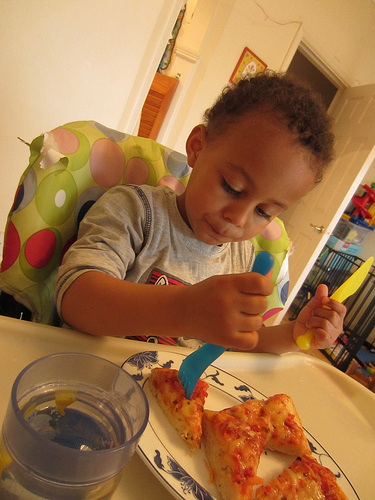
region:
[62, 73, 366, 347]
child eating pizza slices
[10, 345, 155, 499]
cup on the tray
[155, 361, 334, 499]
pizza slices on the plate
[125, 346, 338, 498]
white plate with blue design on border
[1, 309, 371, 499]
tray of the high chair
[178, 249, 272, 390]
blue fork child is eating with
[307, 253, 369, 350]
yellow knife in child's hand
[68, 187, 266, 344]
gray shirt child is wearing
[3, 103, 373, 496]
high chair child is sitting in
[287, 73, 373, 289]
white door to the room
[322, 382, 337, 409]
part of a plate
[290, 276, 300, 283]
part of a door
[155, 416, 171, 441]
edge of a plate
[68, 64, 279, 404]
a child in a high chair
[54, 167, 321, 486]
a child sitting in high chair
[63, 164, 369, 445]
a child eatting in high chair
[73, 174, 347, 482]
a child holding plastic fork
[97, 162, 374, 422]
a child holding a blue fork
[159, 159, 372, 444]
a child holding yellow knife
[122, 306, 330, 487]
food on a plate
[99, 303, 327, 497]
a plate with food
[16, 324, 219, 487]
a drink on the high chair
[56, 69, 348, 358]
toddler eating in a highchair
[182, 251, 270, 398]
blue plastic fork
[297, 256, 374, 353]
yellow plastic knife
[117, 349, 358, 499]
white plate with blue decorations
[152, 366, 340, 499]
pizza cut into small pieces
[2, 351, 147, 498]
clear cup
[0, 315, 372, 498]
white tray of the highchair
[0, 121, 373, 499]
highchair with green and pink circles on it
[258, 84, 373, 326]
white door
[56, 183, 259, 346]
gray shirt on the toddler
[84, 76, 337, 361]
African American boy eating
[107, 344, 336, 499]
Pizza setting on plate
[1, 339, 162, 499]
Cup full of lemon water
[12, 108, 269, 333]
High chair cover with circle pattern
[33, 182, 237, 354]
Boy's shirt sleeve is rolled up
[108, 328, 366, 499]
Blue and white plate under pizza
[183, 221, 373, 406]
Boy is holding plastic silverware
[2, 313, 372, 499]
White high chair tray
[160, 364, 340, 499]
Four small pieces of pizza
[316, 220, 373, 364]
Crib in another room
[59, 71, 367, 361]
child eating pizza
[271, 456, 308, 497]
a slice of pizza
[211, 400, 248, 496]
a slice of pizza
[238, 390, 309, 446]
a slice of pizza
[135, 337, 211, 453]
a slice of pizza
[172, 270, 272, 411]
a blue plastic fork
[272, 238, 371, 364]
a yellow plastic knife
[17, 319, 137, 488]
a glass of water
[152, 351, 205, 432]
sauce on the pizza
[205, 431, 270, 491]
sauce on the pizza